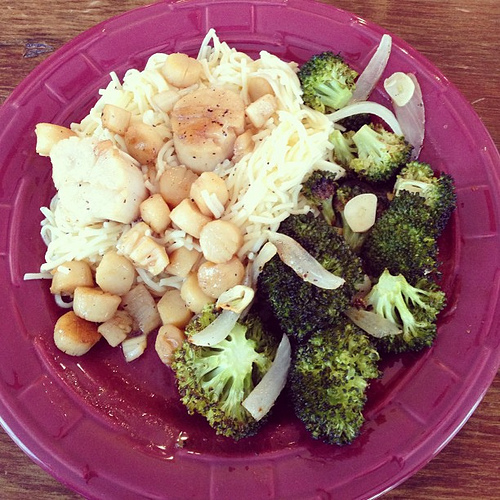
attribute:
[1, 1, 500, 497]
table — brown, wooden, brown color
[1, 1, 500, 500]
plate — plastic, purple color, plastic material, purple, shining, pink, lunch plate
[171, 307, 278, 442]
broccoli — green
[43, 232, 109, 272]
noodle — white, white hue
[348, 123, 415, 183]
broccoli — green, green color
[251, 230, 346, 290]
onion — white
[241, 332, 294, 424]
onion — white, sauteed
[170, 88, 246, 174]
meat — brown